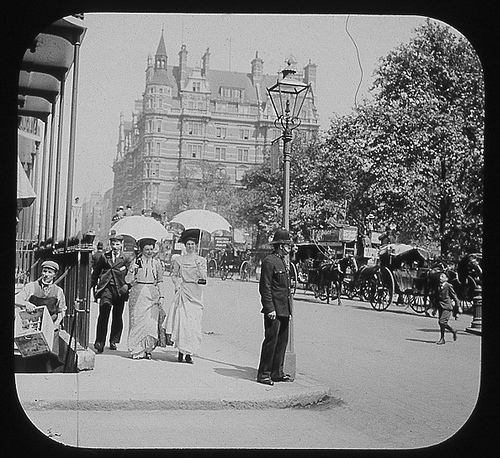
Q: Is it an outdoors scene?
A: Yes, it is outdoors.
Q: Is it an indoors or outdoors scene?
A: It is outdoors.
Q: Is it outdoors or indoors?
A: It is outdoors.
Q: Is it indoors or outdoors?
A: It is outdoors.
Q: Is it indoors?
A: No, it is outdoors.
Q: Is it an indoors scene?
A: No, it is outdoors.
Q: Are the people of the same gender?
A: No, they are both male and female.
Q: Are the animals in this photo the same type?
A: Yes, all the animals are horses.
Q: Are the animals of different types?
A: No, all the animals are horses.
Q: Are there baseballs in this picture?
A: No, there are no baseballs.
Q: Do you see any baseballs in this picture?
A: No, there are no baseballs.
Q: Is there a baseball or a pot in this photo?
A: No, there are no baseballs or pots.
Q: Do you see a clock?
A: No, there are no clocks.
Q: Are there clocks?
A: No, there are no clocks.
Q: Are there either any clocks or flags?
A: No, there are no clocks or flags.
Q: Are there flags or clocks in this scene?
A: No, there are no clocks or flags.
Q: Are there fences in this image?
A: No, there are no fences.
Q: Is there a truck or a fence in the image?
A: No, there are no fences or trucks.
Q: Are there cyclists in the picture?
A: No, there are no cyclists.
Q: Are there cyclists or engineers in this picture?
A: No, there are no cyclists or engineers.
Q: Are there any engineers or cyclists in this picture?
A: No, there are no cyclists or engineers.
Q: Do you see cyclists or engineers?
A: No, there are no cyclists or engineers.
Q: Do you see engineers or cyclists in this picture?
A: No, there are no cyclists or engineers.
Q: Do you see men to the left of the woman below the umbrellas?
A: Yes, there is a man to the left of the woman.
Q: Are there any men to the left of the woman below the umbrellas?
A: Yes, there is a man to the left of the woman.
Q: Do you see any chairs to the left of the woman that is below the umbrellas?
A: No, there is a man to the left of the woman.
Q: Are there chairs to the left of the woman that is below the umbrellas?
A: No, there is a man to the left of the woman.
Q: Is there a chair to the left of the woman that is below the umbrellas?
A: No, there is a man to the left of the woman.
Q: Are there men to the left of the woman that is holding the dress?
A: Yes, there is a man to the left of the woman.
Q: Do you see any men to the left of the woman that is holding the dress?
A: Yes, there is a man to the left of the woman.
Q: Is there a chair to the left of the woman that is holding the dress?
A: No, there is a man to the left of the woman.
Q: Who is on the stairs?
A: The man is on the stairs.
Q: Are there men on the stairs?
A: Yes, there is a man on the stairs.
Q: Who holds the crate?
A: The man holds the crate.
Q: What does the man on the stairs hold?
A: The man holds the crate.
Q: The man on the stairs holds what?
A: The man holds the crate.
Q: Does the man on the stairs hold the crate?
A: Yes, the man holds the crate.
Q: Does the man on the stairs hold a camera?
A: No, the man holds the crate.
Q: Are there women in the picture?
A: Yes, there is a woman.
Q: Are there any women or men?
A: Yes, there is a woman.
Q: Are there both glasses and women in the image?
A: No, there is a woman but no glasses.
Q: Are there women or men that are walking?
A: Yes, the woman is walking.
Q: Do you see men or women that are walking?
A: Yes, the woman is walking.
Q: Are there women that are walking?
A: Yes, there is a woman that is walking.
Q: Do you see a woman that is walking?
A: Yes, there is a woman that is walking.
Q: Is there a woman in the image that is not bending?
A: Yes, there is a woman that is walking.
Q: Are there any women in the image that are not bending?
A: Yes, there is a woman that is walking.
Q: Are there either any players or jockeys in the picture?
A: No, there are no jockeys or players.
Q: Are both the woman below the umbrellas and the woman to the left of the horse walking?
A: Yes, both the woman and the woman are walking.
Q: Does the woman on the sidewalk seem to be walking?
A: Yes, the woman is walking.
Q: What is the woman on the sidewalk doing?
A: The woman is walking.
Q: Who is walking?
A: The woman is walking.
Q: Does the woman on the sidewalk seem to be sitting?
A: No, the woman is walking.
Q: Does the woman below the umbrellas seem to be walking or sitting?
A: The woman is walking.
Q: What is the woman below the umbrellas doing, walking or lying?
A: The woman is walking.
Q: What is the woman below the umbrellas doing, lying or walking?
A: The woman is walking.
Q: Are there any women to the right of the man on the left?
A: Yes, there is a woman to the right of the man.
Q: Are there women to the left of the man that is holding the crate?
A: No, the woman is to the right of the man.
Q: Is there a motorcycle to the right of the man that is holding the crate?
A: No, there is a woman to the right of the man.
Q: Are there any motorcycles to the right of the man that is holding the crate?
A: No, there is a woman to the right of the man.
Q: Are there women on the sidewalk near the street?
A: Yes, there is a woman on the sidewalk.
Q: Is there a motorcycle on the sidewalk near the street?
A: No, there is a woman on the sidewalk.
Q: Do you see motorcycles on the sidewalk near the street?
A: No, there is a woman on the sidewalk.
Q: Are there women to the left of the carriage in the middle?
A: Yes, there is a woman to the left of the carriage.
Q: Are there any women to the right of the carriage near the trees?
A: No, the woman is to the left of the carriage.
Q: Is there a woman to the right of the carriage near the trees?
A: No, the woman is to the left of the carriage.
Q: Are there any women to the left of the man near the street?
A: Yes, there is a woman to the left of the man.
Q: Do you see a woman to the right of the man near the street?
A: No, the woman is to the left of the man.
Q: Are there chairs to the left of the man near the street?
A: No, there is a woman to the left of the man.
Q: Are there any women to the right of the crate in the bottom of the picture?
A: Yes, there is a woman to the right of the crate.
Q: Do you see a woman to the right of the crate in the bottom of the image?
A: Yes, there is a woman to the right of the crate.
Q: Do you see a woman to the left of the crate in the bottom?
A: No, the woman is to the right of the crate.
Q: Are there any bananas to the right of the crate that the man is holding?
A: No, there is a woman to the right of the crate.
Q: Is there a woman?
A: Yes, there is a woman.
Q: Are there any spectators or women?
A: Yes, there is a woman.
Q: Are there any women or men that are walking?
A: Yes, the woman is walking.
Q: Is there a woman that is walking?
A: Yes, there is a woman that is walking.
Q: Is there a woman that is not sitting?
A: Yes, there is a woman that is walking.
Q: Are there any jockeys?
A: No, there are no jockeys.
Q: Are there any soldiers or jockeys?
A: No, there are no jockeys or soldiers.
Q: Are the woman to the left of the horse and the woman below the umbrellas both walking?
A: Yes, both the woman and the woman are walking.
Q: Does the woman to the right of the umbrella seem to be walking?
A: Yes, the woman is walking.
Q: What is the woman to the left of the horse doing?
A: The woman is walking.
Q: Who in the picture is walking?
A: The woman is walking.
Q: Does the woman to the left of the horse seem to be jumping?
A: No, the woman is walking.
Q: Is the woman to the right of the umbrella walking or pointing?
A: The woman is walking.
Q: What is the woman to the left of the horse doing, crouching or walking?
A: The woman is walking.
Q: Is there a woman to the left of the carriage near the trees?
A: Yes, there is a woman to the left of the carriage.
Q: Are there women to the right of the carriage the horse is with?
A: No, the woman is to the left of the carriage.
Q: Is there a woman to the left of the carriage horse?
A: Yes, there is a woman to the left of the horse.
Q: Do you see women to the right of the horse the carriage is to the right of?
A: No, the woman is to the left of the horse.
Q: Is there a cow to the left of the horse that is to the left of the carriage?
A: No, there is a woman to the left of the horse.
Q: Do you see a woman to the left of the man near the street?
A: Yes, there is a woman to the left of the man.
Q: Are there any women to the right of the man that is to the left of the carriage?
A: No, the woman is to the left of the man.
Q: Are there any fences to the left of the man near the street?
A: No, there is a woman to the left of the man.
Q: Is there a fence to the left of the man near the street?
A: No, there is a woman to the left of the man.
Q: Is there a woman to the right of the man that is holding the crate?
A: Yes, there is a woman to the right of the man.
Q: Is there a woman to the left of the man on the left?
A: No, the woman is to the right of the man.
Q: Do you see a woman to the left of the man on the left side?
A: No, the woman is to the right of the man.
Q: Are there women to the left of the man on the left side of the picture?
A: No, the woman is to the right of the man.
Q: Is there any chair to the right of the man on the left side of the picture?
A: No, there is a woman to the right of the man.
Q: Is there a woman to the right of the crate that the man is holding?
A: Yes, there is a woman to the right of the crate.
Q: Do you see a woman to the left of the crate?
A: No, the woman is to the right of the crate.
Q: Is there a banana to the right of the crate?
A: No, there is a woman to the right of the crate.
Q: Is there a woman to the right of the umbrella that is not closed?
A: Yes, there is a woman to the right of the umbrella.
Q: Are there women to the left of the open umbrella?
A: No, the woman is to the right of the umbrella.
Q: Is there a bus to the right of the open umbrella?
A: No, there is a woman to the right of the umbrella.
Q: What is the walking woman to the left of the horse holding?
A: The woman is holding the dress.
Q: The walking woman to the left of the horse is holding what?
A: The woman is holding the dress.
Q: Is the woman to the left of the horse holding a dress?
A: Yes, the woman is holding a dress.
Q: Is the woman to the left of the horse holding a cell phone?
A: No, the woman is holding a dress.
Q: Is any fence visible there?
A: No, there are no fences.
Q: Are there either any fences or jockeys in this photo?
A: No, there are no fences or jockeys.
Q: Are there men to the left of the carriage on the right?
A: Yes, there is a man to the left of the carriage.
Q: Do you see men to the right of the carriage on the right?
A: No, the man is to the left of the carriage.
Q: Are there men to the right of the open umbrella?
A: Yes, there is a man to the right of the umbrella.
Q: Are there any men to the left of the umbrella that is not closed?
A: No, the man is to the right of the umbrella.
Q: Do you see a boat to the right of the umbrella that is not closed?
A: No, there is a man to the right of the umbrella.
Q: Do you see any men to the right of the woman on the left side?
A: Yes, there is a man to the right of the woman.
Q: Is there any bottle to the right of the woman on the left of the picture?
A: No, there is a man to the right of the woman.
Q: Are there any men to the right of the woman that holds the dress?
A: Yes, there is a man to the right of the woman.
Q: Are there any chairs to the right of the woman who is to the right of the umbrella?
A: No, there is a man to the right of the woman.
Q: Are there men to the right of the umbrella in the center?
A: Yes, there is a man to the right of the umbrella.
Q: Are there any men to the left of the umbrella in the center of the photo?
A: No, the man is to the right of the umbrella.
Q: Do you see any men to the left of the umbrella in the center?
A: No, the man is to the right of the umbrella.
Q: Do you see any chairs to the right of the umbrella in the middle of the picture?
A: No, there is a man to the right of the umbrella.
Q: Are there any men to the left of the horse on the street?
A: Yes, there is a man to the left of the horse.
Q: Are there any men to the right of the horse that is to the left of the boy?
A: No, the man is to the left of the horse.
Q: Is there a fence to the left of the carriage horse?
A: No, there is a man to the left of the horse.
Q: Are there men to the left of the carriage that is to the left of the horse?
A: Yes, there is a man to the left of the carriage.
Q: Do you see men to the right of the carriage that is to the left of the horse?
A: No, the man is to the left of the carriage.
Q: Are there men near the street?
A: Yes, there is a man near the street.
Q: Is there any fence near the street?
A: No, there is a man near the street.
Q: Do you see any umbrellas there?
A: Yes, there are umbrellas.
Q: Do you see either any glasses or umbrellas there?
A: Yes, there are umbrellas.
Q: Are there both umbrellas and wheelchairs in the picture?
A: No, there are umbrellas but no wheelchairs.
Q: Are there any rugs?
A: No, there are no rugs.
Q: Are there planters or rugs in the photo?
A: No, there are no rugs or planters.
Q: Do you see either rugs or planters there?
A: No, there are no rugs or planters.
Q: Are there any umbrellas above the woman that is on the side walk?
A: Yes, there are umbrellas above the woman.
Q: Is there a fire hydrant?
A: Yes, there is a fire hydrant.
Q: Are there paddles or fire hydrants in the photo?
A: Yes, there is a fire hydrant.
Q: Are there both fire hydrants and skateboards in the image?
A: No, there is a fire hydrant but no skateboards.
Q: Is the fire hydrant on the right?
A: Yes, the fire hydrant is on the right of the image.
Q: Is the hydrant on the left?
A: No, the hydrant is on the right of the image.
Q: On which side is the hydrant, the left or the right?
A: The hydrant is on the right of the image.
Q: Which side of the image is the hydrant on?
A: The hydrant is on the right of the image.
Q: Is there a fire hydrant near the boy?
A: Yes, there is a fire hydrant near the boy.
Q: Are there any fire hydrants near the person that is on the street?
A: Yes, there is a fire hydrant near the boy.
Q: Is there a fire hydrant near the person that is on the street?
A: Yes, there is a fire hydrant near the boy.